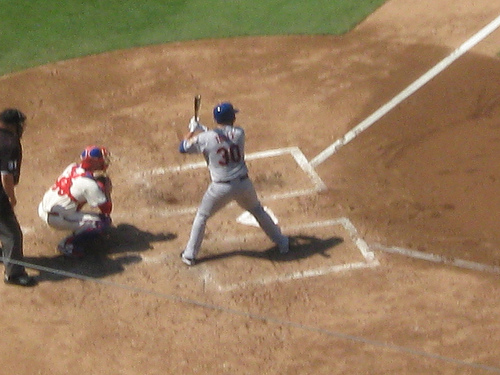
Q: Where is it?
A: This is at the field.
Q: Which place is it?
A: It is a field.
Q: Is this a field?
A: Yes, it is a field.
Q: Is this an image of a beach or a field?
A: It is showing a field.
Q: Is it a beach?
A: No, it is a field.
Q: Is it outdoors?
A: Yes, it is outdoors.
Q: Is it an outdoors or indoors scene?
A: It is outdoors.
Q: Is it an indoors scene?
A: No, it is outdoors.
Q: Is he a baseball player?
A: Yes, this is a baseball player.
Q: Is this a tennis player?
A: No, this is a baseball player.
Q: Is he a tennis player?
A: No, this is a baseball player.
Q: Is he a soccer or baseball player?
A: This is a baseball player.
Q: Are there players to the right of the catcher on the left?
A: Yes, there is a player to the right of the catcher.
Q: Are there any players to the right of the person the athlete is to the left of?
A: Yes, there is a player to the right of the catcher.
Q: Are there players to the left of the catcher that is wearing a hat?
A: No, the player is to the right of the catcher.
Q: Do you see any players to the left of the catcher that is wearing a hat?
A: No, the player is to the right of the catcher.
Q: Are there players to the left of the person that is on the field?
A: No, the player is to the right of the catcher.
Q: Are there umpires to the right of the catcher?
A: No, there is a player to the right of the catcher.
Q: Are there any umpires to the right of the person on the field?
A: No, there is a player to the right of the catcher.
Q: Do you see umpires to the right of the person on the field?
A: No, there is a player to the right of the catcher.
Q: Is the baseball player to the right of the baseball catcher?
A: Yes, the player is to the right of the catcher.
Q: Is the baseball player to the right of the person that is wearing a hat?
A: Yes, the player is to the right of the catcher.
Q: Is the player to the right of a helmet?
A: No, the player is to the right of the catcher.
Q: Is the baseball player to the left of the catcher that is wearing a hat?
A: No, the player is to the right of the catcher.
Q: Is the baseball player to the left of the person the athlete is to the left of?
A: No, the player is to the right of the catcher.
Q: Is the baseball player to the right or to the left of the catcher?
A: The player is to the right of the catcher.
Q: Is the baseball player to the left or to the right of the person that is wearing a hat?
A: The player is to the right of the catcher.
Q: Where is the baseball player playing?
A: The player is playing on the field.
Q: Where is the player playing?
A: The player is playing on the field.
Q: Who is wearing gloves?
A: The player is wearing gloves.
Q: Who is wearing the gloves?
A: The player is wearing gloves.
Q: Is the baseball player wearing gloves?
A: Yes, the player is wearing gloves.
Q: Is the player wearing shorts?
A: No, the player is wearing gloves.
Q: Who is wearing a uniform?
A: The player is wearing a uniform.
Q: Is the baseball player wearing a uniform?
A: Yes, the player is wearing a uniform.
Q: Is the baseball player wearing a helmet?
A: No, the player is wearing a uniform.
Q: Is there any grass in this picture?
A: Yes, there is grass.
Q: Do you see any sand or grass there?
A: Yes, there is grass.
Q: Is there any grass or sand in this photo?
A: Yes, there is grass.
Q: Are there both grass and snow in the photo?
A: No, there is grass but no snow.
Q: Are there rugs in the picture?
A: No, there are no rugs.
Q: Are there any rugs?
A: No, there are no rugs.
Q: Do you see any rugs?
A: No, there are no rugs.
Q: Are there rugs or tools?
A: No, there are no rugs or tools.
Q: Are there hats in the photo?
A: Yes, there is a hat.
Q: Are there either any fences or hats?
A: Yes, there is a hat.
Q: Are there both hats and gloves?
A: Yes, there are both a hat and gloves.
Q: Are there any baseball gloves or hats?
A: Yes, there is a baseball hat.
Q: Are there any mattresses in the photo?
A: No, there are no mattresses.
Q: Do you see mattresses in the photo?
A: No, there are no mattresses.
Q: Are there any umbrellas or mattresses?
A: No, there are no mattresses or umbrellas.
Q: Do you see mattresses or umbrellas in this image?
A: No, there are no mattresses or umbrellas.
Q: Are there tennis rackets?
A: No, there are no tennis rackets.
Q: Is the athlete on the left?
A: Yes, the athlete is on the left of the image.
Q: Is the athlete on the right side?
A: No, the athlete is on the left of the image.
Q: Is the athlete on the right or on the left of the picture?
A: The athlete is on the left of the image.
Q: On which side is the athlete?
A: The athlete is on the left of the image.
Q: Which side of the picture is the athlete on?
A: The athlete is on the left of the image.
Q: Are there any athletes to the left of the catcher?
A: Yes, there is an athlete to the left of the catcher.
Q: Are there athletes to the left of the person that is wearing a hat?
A: Yes, there is an athlete to the left of the catcher.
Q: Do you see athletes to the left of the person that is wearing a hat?
A: Yes, there is an athlete to the left of the catcher.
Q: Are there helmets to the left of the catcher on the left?
A: No, there is an athlete to the left of the catcher.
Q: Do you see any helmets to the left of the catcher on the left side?
A: No, there is an athlete to the left of the catcher.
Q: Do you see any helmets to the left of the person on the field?
A: No, there is an athlete to the left of the catcher.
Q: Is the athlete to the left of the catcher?
A: Yes, the athlete is to the left of the catcher.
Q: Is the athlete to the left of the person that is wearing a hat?
A: Yes, the athlete is to the left of the catcher.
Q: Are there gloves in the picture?
A: Yes, there are gloves.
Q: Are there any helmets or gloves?
A: Yes, there are gloves.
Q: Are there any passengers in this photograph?
A: No, there are no passengers.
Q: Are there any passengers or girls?
A: No, there are no passengers or girls.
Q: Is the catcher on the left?
A: Yes, the catcher is on the left of the image.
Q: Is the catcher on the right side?
A: No, the catcher is on the left of the image.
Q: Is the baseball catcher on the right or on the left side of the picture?
A: The catcher is on the left of the image.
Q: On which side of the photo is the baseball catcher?
A: The catcher is on the left of the image.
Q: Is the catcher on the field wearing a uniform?
A: Yes, the catcher is wearing a uniform.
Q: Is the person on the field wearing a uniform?
A: Yes, the catcher is wearing a uniform.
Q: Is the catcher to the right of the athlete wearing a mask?
A: No, the catcher is wearing a uniform.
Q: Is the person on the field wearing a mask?
A: No, the catcher is wearing a uniform.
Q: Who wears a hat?
A: The catcher wears a hat.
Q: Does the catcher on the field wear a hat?
A: Yes, the catcher wears a hat.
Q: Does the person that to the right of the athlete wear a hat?
A: Yes, the catcher wears a hat.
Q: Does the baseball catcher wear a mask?
A: No, the catcher wears a hat.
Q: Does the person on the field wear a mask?
A: No, the catcher wears a hat.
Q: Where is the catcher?
A: The catcher is on the field.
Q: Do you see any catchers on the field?
A: Yes, there is a catcher on the field.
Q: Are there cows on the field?
A: No, there is a catcher on the field.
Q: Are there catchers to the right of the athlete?
A: Yes, there is a catcher to the right of the athlete.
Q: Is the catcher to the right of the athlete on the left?
A: Yes, the catcher is to the right of the athlete.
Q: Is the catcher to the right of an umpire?
A: No, the catcher is to the right of the athlete.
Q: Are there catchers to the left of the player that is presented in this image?
A: Yes, there is a catcher to the left of the player.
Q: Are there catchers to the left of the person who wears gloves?
A: Yes, there is a catcher to the left of the player.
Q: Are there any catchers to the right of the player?
A: No, the catcher is to the left of the player.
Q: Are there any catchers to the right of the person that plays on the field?
A: No, the catcher is to the left of the player.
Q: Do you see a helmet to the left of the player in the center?
A: No, there is a catcher to the left of the player.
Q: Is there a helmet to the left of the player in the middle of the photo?
A: No, there is a catcher to the left of the player.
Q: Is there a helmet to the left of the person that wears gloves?
A: No, there is a catcher to the left of the player.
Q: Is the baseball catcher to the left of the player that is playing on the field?
A: Yes, the catcher is to the left of the player.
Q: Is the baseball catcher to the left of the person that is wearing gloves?
A: Yes, the catcher is to the left of the player.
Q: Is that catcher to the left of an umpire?
A: No, the catcher is to the left of the player.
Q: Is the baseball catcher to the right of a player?
A: No, the catcher is to the left of a player.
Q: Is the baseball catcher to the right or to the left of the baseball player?
A: The catcher is to the left of the player.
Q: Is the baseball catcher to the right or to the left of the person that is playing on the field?
A: The catcher is to the left of the player.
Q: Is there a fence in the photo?
A: No, there are no fences.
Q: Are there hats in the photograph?
A: Yes, there is a hat.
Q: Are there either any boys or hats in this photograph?
A: Yes, there is a hat.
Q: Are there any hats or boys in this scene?
A: Yes, there is a hat.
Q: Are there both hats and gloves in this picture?
A: Yes, there are both a hat and gloves.